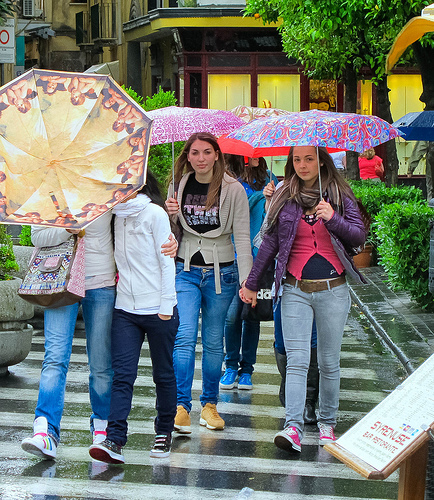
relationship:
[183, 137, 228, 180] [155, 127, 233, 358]
face of a woman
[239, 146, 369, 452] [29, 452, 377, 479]
girl walking on sidewalk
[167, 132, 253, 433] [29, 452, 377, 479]
person walking on sidewalk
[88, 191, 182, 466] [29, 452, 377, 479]
person walking on sidewalk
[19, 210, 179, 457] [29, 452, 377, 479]
person walking on sidewalk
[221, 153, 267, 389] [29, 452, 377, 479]
person walking on sidewalk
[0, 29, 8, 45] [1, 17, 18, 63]
letter on sign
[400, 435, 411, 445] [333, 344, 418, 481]
letter on sign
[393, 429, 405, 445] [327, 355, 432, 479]
letter on sign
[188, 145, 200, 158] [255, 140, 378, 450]
eye of woman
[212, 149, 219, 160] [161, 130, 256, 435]
ear of person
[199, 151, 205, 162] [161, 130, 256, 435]
nose of person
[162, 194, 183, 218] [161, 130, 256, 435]
hand of person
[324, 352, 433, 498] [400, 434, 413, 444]
sign has letter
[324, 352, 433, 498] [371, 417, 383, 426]
sign has letter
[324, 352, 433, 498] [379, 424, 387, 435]
sign has letter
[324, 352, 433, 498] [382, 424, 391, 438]
sign has letter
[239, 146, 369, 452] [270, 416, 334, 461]
girl has on shoes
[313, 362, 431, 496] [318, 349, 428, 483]
stand holding sign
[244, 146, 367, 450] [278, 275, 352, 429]
girl has on pants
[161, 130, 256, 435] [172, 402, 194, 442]
person has on shoe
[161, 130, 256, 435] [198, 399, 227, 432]
person has on shoe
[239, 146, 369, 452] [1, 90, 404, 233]
girl holding umbrella's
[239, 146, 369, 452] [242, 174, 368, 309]
girl has on jacket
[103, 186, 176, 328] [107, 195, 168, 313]
person has on sweater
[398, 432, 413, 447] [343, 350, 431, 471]
letter on sign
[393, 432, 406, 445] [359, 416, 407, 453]
letter on sign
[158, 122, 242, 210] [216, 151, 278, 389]
head of person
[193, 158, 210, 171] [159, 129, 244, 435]
lips of woman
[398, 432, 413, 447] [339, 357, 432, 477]
letter on sign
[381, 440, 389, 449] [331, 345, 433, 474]
letter on sign